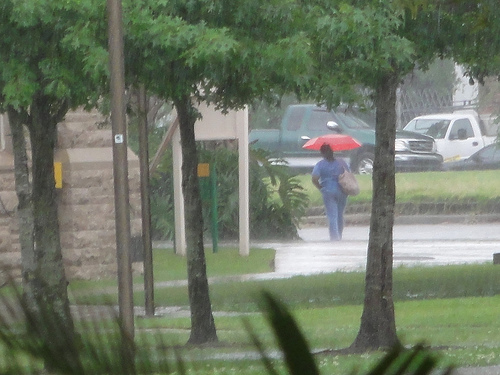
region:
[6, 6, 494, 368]
picture taken outdoors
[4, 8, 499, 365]
picture taken during the day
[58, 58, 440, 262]
it is raining outside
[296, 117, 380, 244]
a woman holds an umbrella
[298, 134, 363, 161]
umbrella is red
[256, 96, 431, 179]
the truck is green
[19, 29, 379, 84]
tree full of leaves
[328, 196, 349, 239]
woman wears blue pants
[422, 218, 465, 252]
the road is wet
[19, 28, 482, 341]
a stormy day outside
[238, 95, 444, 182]
The truck is green.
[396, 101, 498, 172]
The truck is white.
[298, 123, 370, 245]
The woman is carrying an umbrella.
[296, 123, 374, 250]
The umbrella is red.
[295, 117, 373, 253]
The umbrella is open.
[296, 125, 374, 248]
The woman is carrying a shoulder bag.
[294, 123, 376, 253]
The woman is wearing pants.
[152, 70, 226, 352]
The tree trunk is straight.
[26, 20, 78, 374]
The tree trunk is straight.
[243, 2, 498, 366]
The leaves on the tree are green.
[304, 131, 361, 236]
woman walking in the rain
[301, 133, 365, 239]
woman holding a red umbrella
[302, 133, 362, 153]
red umbrella over the woman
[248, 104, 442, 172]
green truck parked in the lot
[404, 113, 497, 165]
white truck parked in the lot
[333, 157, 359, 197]
brown purse on the woman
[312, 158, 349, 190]
blue shirt on the woman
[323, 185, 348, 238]
blue jeans on the woman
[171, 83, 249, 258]
white sign next to the street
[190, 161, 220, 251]
yellow sign under the white sign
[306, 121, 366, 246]
woman with red umbrella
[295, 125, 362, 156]
red umbrella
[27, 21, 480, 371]
three trees in a yard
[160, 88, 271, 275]
back of white sign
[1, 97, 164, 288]
light beige colored stone blocks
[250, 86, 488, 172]
two trucks on the side of the road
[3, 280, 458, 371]
palm trees near the foreground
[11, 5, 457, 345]
pouring rain on the ground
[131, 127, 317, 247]
woman walks past palm trees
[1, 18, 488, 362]
trees in the grass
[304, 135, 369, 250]
a woman wearing a blue outfit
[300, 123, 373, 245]
a woman carrying a red umbrella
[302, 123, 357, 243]
a woman walking through the park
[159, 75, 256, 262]
a tall white wooden sign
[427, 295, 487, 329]
green grass of the ground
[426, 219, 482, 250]
black asphalt surface of the walkway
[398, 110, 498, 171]
a white truck on the street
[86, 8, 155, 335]
a black metal pole in the park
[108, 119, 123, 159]
a white sticker on a black pole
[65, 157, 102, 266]
tan stone wall of a building